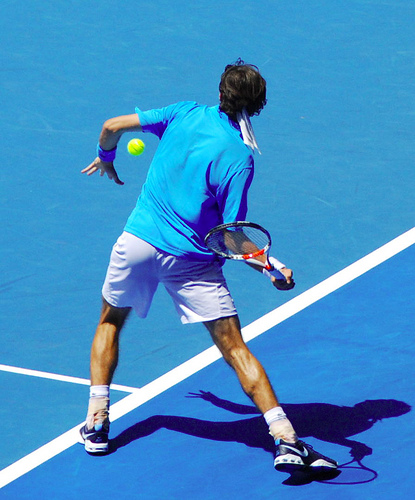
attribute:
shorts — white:
[41, 214, 261, 346]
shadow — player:
[98, 388, 412, 485]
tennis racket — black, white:
[207, 222, 287, 292]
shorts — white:
[101, 225, 239, 325]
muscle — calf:
[235, 360, 271, 396]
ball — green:
[123, 134, 147, 157]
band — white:
[234, 108, 263, 148]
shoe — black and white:
[78, 419, 111, 453]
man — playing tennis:
[42, 26, 327, 303]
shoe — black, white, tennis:
[269, 436, 343, 481]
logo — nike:
[279, 441, 310, 457]